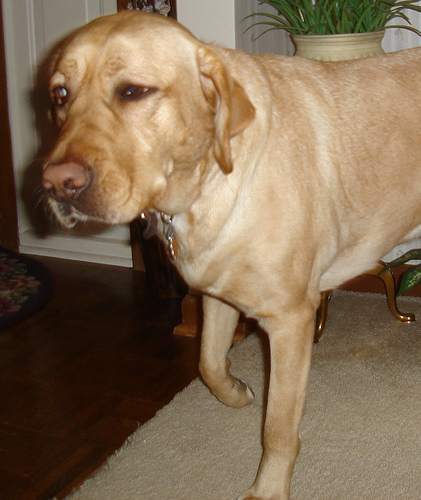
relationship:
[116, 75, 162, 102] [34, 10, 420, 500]
eye on dog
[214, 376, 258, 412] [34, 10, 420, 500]
paw on dog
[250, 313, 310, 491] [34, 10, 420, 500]
leg on dog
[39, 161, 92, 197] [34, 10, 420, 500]
nose on dog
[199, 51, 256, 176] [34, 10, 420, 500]
ear on dog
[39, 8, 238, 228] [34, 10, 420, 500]
head on dog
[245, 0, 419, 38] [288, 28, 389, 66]
plant in pot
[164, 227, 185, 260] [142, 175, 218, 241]
tag on collar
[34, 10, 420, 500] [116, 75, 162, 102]
dog with an eye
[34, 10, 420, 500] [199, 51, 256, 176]
dog with an ear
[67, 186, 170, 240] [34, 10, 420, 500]
mouth on dog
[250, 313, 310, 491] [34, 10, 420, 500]
leg on tan dog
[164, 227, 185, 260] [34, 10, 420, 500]
tag on dog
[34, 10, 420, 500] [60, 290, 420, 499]
dog on carpet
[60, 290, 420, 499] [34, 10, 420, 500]
carpet with a dog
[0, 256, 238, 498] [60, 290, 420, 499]
floor by carpet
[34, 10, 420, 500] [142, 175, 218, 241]
dog has a collar